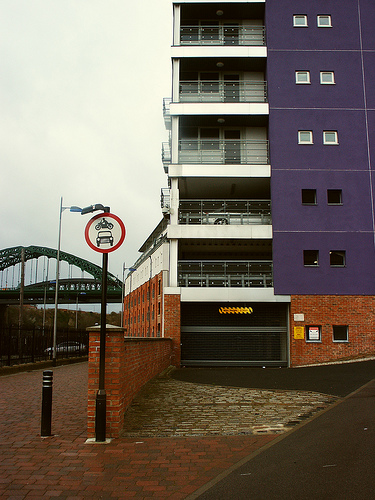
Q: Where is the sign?
A: Pole.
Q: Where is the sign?
A: On pole.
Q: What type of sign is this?
A: Circle street.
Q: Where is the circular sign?
A: On pole.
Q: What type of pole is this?
A: Metal.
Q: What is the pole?
A: On the walkway.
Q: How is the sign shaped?
A: Circular.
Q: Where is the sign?
A: Outside on the walkway.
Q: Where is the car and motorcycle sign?
A: On the pole.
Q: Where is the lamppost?
A: Sidewalk.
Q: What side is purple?
A: The side of the parking garage.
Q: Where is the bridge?
A: Located behind the parking garage.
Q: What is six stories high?
A: The building.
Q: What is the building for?
A: Apartments.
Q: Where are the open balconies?
A: On the apartment building.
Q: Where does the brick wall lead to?
A: The parking garage.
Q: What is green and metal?
A: The arched bridge.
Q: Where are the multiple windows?
A: On the back wall.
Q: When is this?
A: During the day.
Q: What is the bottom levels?
A: A parking garage.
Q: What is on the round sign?
A: A motorcycle and car.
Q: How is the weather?
A: Cloudy.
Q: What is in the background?
A: A bridge.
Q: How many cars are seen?
A: Two.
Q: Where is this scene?
A: On the sidewalk.